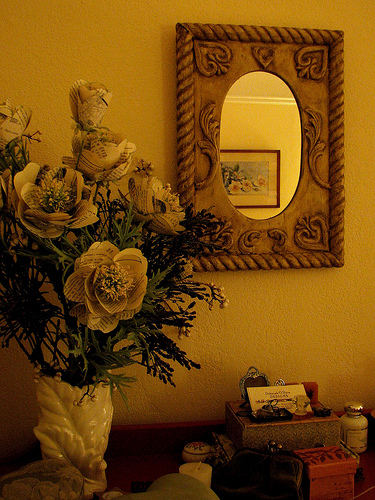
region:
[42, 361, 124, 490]
white ceramic vase with a leaf design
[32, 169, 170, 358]
roses made from newspaper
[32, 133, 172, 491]
fake roses in a vase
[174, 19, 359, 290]
decorative mirror hanging on the wall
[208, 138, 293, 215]
reflection of art work in mirror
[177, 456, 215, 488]
white votive candle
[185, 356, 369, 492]
knick knacks on the shelf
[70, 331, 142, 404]
green plastic leaves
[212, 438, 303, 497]
small black coin purse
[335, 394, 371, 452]
small white jar with a silver cap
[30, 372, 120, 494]
THE VASE IS WHITE AND SHINY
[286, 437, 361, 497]
THE BOX IS CARVED WOOD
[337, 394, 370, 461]
THE BOTTLE OF LOTION HAS A SILVER TOP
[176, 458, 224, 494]
THE VOTIVE CANDLE IS WHITE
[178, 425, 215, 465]
THE PORCELAIN BOX HAS FLOWERS ON IT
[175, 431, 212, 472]
THE BOX IS PORCELAIN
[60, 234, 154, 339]
THE FLOWER IS MADE FROM NEWSPRINT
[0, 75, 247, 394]
THE FLOWERS ARE IN THE VASE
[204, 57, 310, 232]
THE MIRROR IS AN OVAL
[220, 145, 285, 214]
THE PICTURE IS A REFLECTION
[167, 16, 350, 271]
a mirror on the wall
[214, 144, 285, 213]
a picture reflection in the mirror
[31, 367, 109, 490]
a white vase on the dresser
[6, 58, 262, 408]
flowers in the vase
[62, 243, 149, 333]
recycled paper in the flower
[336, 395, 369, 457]
a bottle on the dresser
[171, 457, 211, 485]
a candle on the dresser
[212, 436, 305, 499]
a coin purse on the dresser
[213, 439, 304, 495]
the coin purse is black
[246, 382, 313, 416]
a business card on the dresser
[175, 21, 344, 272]
Decorative framed mirror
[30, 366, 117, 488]
White decorative vase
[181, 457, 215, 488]
White candle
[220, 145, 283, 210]
Reflection in mirror of picture hanging on adjacent wall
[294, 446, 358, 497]
Decorative box with cover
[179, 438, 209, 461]
Decorative container with cover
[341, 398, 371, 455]
Round bottle with silver cover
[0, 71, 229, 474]
Artificial flowers and greens in white vase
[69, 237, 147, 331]
Artificial flower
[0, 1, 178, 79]
Yellow painted wall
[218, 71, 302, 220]
oval shaped mirror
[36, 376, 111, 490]
white glass flower vase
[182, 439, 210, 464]
small round case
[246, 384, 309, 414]
stack of business cards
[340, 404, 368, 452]
jar with a silver lid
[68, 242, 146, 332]
decorative flower made of paper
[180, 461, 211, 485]
candle that has not been lit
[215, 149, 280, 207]
framed art on the wall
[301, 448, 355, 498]
square decorative box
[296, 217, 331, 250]
heart accent on mirror frame